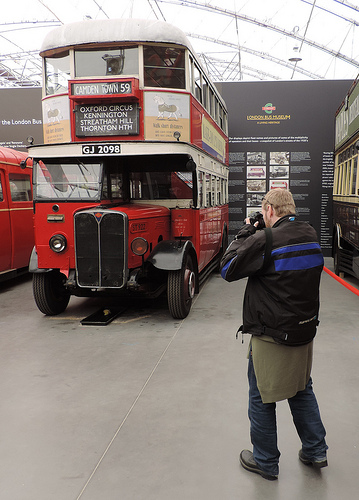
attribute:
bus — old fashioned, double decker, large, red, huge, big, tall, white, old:
[28, 16, 233, 322]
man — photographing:
[218, 185, 331, 484]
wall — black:
[2, 72, 359, 263]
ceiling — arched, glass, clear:
[0, 1, 358, 87]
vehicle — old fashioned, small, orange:
[1, 143, 40, 292]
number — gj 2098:
[79, 143, 122, 157]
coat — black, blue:
[220, 212, 322, 348]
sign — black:
[241, 98, 299, 132]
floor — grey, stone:
[2, 253, 358, 499]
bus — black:
[328, 68, 358, 293]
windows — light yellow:
[332, 137, 359, 199]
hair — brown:
[261, 190, 297, 223]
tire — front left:
[167, 249, 197, 320]